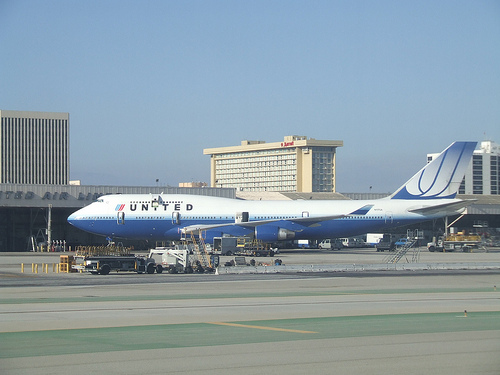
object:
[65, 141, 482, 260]
airline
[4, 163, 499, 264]
airport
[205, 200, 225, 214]
white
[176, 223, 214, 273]
stairs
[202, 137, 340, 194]
building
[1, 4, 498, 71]
sky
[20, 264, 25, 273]
poles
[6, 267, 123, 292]
parking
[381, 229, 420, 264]
stair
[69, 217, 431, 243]
blue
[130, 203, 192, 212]
name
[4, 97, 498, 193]
background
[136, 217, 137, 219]
windows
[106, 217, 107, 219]
window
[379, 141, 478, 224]
tail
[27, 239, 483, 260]
road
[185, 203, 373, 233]
wing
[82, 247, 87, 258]
cones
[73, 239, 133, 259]
barriers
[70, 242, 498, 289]
tarmac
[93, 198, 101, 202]
cockpit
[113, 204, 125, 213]
logo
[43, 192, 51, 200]
word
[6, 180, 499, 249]
building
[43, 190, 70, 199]
air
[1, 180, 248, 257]
terminal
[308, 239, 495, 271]
runway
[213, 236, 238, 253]
luggage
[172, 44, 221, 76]
blue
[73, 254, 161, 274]
cart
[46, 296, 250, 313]
concrete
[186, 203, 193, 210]
text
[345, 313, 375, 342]
paint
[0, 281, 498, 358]
ground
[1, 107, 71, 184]
building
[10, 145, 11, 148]
windows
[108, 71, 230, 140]
bright